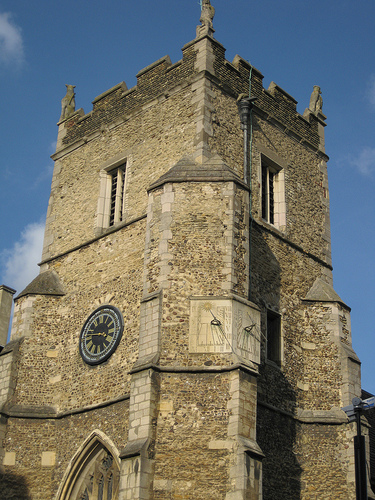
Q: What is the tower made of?
A: Brick.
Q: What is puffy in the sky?
A: Clouds.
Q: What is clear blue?
A: The sky.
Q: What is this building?
A: Castle.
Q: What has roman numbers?
A: Clock.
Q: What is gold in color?
A: Numbers.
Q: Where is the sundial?
A: On the corner.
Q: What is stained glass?
A: Windows.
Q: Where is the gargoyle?
A: On the roof.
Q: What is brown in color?
A: Building.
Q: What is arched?
A: Doorway.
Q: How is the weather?
A: The sky is clear and it is sunny.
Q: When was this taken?
A: During the day.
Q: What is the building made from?
A: Brick.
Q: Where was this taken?
A: Outside of an old building.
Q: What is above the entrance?
A: A clock.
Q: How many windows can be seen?
A: Three.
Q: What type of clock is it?
A: An analog clock.